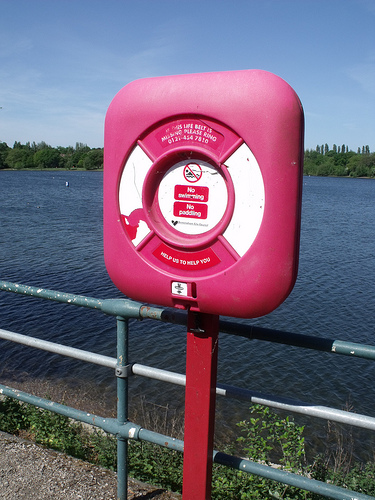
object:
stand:
[183, 311, 212, 496]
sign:
[103, 68, 302, 312]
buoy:
[64, 179, 70, 187]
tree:
[325, 143, 329, 157]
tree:
[340, 145, 346, 157]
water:
[0, 168, 373, 458]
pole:
[116, 296, 128, 499]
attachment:
[101, 296, 144, 321]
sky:
[0, 0, 374, 152]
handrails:
[0, 278, 373, 499]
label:
[171, 280, 187, 297]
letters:
[156, 118, 220, 149]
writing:
[155, 250, 217, 267]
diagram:
[115, 110, 266, 282]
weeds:
[234, 401, 312, 493]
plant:
[0, 395, 30, 434]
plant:
[26, 403, 81, 455]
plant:
[89, 428, 157, 475]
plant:
[312, 434, 374, 492]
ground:
[2, 396, 303, 499]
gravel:
[0, 434, 186, 496]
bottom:
[103, 236, 296, 317]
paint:
[15, 282, 43, 296]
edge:
[204, 315, 215, 499]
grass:
[2, 371, 190, 438]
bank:
[134, 442, 364, 499]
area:
[0, 141, 374, 178]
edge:
[0, 378, 252, 499]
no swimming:
[184, 162, 204, 183]